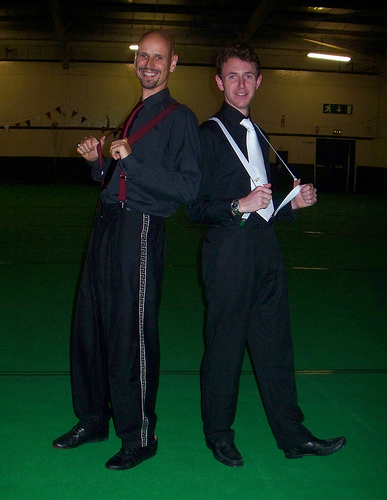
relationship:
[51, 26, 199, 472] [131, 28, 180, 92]
man has head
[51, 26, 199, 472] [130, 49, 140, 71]
man with ear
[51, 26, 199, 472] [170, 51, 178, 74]
man with ear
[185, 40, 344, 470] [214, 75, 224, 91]
man with ear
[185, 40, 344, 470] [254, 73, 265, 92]
man with ear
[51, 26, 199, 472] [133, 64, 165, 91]
man has facial hair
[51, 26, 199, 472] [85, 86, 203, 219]
man wearing shirt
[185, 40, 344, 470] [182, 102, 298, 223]
man wearing shirt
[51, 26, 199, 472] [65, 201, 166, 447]
man wearing dress pants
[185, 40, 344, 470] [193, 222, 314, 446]
man wearing dress pants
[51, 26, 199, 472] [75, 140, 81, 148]
man wearing ring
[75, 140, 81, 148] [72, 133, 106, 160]
ring on right hand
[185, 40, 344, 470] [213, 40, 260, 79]
man with hair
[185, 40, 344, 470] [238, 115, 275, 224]
man wearing tie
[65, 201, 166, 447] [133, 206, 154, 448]
dress pants have stripe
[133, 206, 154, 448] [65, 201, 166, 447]
stripe on side of dress pants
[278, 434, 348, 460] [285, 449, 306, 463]
shoe has heel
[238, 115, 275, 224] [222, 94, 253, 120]
tie around neck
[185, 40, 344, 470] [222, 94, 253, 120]
man has neck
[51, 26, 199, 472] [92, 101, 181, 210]
man wearing suspenders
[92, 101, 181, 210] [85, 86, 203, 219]
suspenders are over shirt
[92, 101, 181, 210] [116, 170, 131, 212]
suspenders have buckles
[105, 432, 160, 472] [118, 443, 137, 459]
shoe has laces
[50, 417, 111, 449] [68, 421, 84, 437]
shoe has laces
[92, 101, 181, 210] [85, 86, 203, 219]
suspenders on top of shirt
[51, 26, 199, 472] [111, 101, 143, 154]
man wearing tie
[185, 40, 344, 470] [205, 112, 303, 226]
man wearing suspenders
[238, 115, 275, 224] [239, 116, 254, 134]
tie has knot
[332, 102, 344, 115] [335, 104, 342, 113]
sign with arrow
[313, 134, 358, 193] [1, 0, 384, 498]
door of room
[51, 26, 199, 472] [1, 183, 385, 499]
man standing on floor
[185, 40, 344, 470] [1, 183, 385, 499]
man standing on floor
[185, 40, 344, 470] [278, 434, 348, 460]
man kicking up shoe